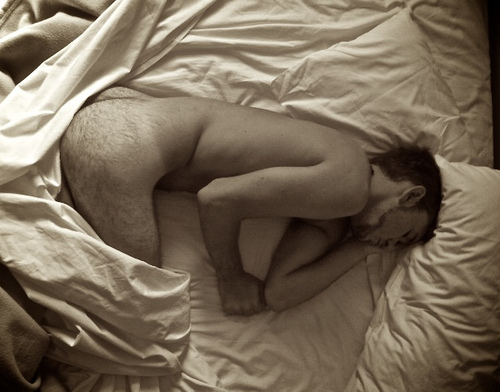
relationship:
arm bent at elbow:
[192, 166, 365, 325] [199, 160, 369, 322]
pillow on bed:
[398, 259, 488, 334] [0, 5, 498, 390]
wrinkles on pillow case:
[426, 188, 483, 345] [345, 151, 497, 390]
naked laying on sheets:
[61, 87, 434, 252] [48, 18, 473, 70]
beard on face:
[355, 210, 395, 240] [352, 200, 431, 250]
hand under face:
[314, 241, 393, 283] [355, 215, 440, 253]